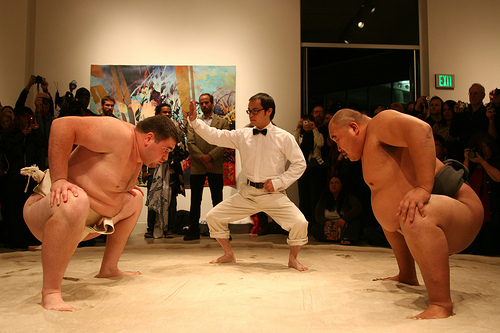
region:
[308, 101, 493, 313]
Sumo wrestler bowing to opponent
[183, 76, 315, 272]
the sumo referee called a Gyoji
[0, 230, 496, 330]
the wrestling ring called the dohyo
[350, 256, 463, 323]
sumo wrestler's feet in the sand of the dohyo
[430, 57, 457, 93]
green exit light near doorway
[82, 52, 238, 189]
Large picture hangs on wall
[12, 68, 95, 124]
people taking pictures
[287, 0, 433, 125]
the exit has a double doorway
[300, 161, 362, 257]
one spectator sits on the floor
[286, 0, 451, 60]
ceiling lights reflected in the transom window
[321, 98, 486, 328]
a sumo wrestler with a black loincloth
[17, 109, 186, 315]
a sumo wrestler with a white loincloth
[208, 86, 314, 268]
a referee in a white shirt and black bowtie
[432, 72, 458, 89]
a green exit sign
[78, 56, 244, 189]
a large painting on a wall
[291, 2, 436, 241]
an open doorway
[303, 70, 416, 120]
a row of windows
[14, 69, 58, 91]
a camera held up high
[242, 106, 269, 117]
glasses on a referee's face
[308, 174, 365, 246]
a woman sitting on the floor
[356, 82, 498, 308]
a sumo wrestler in black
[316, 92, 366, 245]
a sumo wrestler in black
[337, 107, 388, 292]
a sumo wrestler in black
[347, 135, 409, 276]
a sumo wrestler in black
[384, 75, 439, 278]
a sumo wrestler in black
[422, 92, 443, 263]
a sumo wrestler in black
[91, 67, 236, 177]
painting on the white wall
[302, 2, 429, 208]
nighttime outside glass window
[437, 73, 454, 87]
green and white exit sign on wall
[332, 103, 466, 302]
sumo wrestler on right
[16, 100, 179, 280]
sumo wrestler on left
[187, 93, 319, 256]
sumo referee in all white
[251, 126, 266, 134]
black bow tie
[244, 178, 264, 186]
black belt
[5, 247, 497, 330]
sand covered arena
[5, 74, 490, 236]
crowd of spectators behind wrestlers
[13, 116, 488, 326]
two sumo wrestlers ready for a match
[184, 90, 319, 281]
the referree of the sumo wrestling match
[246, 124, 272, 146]
black bow tie of the referree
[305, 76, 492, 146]
many spectators to the right of the ring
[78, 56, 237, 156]
an art piece on the wall behind the wrestlers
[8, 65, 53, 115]
a camera being held in the air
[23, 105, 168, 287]
a sumo wrestler in white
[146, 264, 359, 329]
the tan mat for the wrestling ring